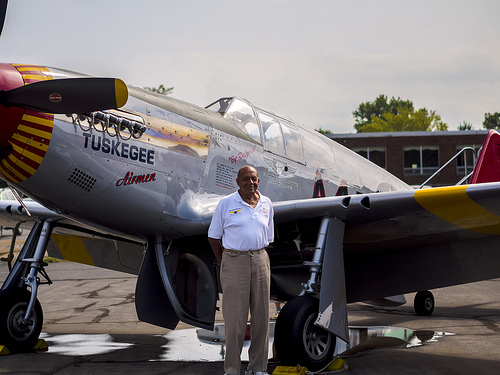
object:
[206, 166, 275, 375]
man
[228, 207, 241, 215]
design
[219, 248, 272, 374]
pants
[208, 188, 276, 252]
shirt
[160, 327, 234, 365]
puddle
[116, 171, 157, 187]
print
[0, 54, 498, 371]
jet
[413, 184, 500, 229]
stripe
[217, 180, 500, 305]
wing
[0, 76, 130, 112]
propeller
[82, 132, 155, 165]
lettering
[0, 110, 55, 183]
stripes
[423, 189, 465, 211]
paint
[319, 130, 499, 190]
building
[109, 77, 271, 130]
cockpit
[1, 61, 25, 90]
nose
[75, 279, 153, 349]
ground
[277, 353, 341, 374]
brake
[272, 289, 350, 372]
gear